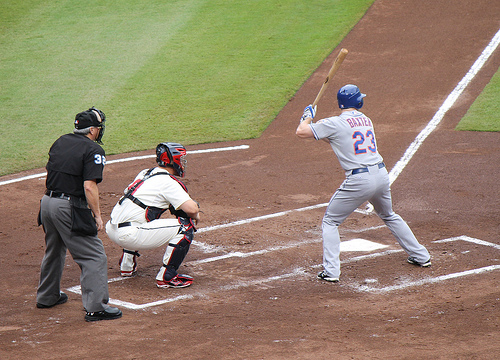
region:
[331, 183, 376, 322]
This man is wearing a pair of gray pants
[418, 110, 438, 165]
There is a white line on the field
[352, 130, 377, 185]
This player has the number 23 here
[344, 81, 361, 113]
This man is wearing a blue helmet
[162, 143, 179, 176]
This person is wearing a helmet too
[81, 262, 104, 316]
The umpire is wearing grey pants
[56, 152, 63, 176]
The umpire is wearing a black shirt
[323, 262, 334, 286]
This man is wearing a pair of black shoes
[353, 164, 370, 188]
This man is wearing a blue belt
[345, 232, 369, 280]
There is a white base here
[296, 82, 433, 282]
a man wearing a gray colored unifrom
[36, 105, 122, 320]
a man wearing gray and black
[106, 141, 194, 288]
a man wearing red, black, and white sneakers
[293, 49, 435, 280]
a man holding a wooden bat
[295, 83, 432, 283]
a man wearing a blue helmet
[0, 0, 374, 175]
grass growing on the field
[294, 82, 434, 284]
a man with the number 23 on his back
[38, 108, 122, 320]
the umpire is wearing a face mask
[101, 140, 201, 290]
the catcher is squatted down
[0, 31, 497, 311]
white lines on the ball field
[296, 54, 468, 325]
This is a person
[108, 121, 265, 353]
This is a person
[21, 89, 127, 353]
This is a person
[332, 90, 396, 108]
Man wearing blue helmet.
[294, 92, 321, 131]
Man wearing blue and white gloves.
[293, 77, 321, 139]
Man holding baseball bat.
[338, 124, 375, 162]
Man wearing gray jersey.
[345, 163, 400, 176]
Man wearing blue belt.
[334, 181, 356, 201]
Man wearing gray pants.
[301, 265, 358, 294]
Man wearing tennis shoes.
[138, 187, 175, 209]
Man wearing white shirt.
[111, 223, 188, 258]
Man wearing white pants.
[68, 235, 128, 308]
Man wearing gray pants.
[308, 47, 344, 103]
a brown baseball bat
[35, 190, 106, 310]
a grey pair of pants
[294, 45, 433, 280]
a baseball player at bat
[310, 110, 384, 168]
a grey baseball jersey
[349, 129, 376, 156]
player number 23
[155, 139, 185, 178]
a grey and red catcher's mask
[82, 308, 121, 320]
a man's black shoe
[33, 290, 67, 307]
a man's black shoe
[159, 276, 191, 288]
a red white and blue shoe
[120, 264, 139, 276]
a red white and blue shoe